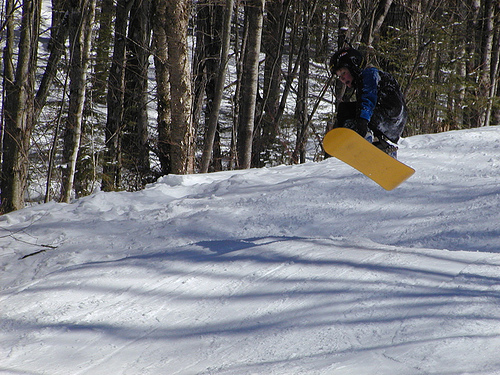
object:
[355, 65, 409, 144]
coat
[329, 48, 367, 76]
helmet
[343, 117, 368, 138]
boot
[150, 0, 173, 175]
tree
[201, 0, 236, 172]
tree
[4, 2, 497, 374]
hill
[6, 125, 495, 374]
slope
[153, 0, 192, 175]
tree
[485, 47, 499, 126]
tree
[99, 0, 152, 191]
tree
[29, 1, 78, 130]
tree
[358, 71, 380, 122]
arm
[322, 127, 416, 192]
board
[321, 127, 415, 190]
yellow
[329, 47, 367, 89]
head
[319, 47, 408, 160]
boy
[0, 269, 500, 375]
snow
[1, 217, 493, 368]
ground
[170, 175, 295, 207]
snow clump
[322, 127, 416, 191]
snowboard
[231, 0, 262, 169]
tree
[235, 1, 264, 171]
tree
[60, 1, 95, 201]
tree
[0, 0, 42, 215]
tree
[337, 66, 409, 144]
jacket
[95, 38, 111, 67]
moss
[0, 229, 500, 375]
shadows